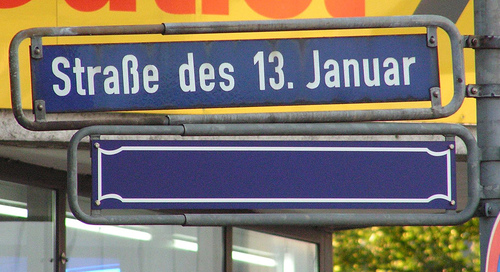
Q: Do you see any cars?
A: No, there are no cars.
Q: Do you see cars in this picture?
A: No, there are no cars.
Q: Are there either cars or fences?
A: No, there are no cars or fences.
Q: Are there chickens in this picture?
A: No, there are no chickens.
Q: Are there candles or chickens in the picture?
A: No, there are no chickens or candles.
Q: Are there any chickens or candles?
A: No, there are no chickens or candles.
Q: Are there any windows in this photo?
A: Yes, there are windows.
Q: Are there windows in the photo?
A: Yes, there are windows.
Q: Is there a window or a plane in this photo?
A: Yes, there are windows.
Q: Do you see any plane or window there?
A: Yes, there are windows.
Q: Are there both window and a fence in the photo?
A: No, there are windows but no fences.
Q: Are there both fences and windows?
A: No, there are windows but no fences.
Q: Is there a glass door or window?
A: Yes, there are glass windows.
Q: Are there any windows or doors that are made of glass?
A: Yes, the windows are made of glass.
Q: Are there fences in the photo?
A: No, there are no fences.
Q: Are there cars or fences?
A: No, there are no fences or cars.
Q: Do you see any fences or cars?
A: No, there are no fences or cars.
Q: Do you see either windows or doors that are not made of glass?
A: No, there are windows but they are made of glass.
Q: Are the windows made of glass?
A: Yes, the windows are made of glass.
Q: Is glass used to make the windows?
A: Yes, the windows are made of glass.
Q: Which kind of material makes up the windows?
A: The windows are made of glass.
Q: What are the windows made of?
A: The windows are made of glass.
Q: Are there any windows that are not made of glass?
A: No, there are windows but they are made of glass.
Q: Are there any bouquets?
A: No, there are no bouquets.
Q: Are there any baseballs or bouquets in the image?
A: No, there are no bouquets or baseballs.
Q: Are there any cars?
A: No, there are no cars.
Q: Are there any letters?
A: Yes, there are letters.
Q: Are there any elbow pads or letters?
A: Yes, there are letters.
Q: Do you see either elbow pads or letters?
A: Yes, there are letters.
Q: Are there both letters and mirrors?
A: No, there are letters but no mirrors.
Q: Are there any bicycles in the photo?
A: No, there are no bicycles.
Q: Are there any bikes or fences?
A: No, there are no bikes or fences.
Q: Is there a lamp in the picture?
A: No, there are no lamps.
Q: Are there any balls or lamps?
A: No, there are no lamps or balls.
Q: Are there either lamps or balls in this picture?
A: No, there are no lamps or balls.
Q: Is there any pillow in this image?
A: No, there are no pillows.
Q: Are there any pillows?
A: No, there are no pillows.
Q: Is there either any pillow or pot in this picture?
A: No, there are no pillows or pots.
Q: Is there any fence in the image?
A: No, there are no fences.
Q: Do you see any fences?
A: No, there are no fences.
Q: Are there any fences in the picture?
A: No, there are no fences.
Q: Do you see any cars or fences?
A: No, there are no fences or cars.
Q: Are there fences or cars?
A: No, there are no fences or cars.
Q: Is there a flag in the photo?
A: No, there are no flags.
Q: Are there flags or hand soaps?
A: No, there are no flags or hand soaps.